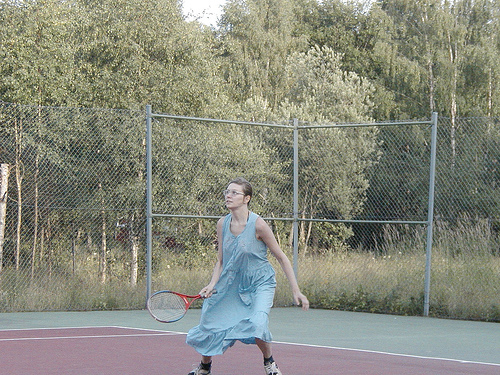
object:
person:
[187, 178, 309, 374]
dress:
[184, 209, 280, 357]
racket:
[146, 288, 215, 325]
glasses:
[220, 189, 253, 199]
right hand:
[198, 281, 215, 301]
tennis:
[0, 303, 499, 375]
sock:
[264, 354, 277, 363]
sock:
[199, 362, 215, 370]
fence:
[0, 115, 499, 322]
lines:
[0, 332, 187, 341]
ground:
[0, 305, 499, 375]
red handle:
[178, 293, 202, 308]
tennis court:
[0, 304, 498, 374]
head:
[222, 177, 258, 208]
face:
[221, 184, 243, 207]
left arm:
[255, 217, 302, 292]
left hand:
[290, 288, 310, 310]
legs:
[255, 340, 274, 367]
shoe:
[264, 362, 285, 374]